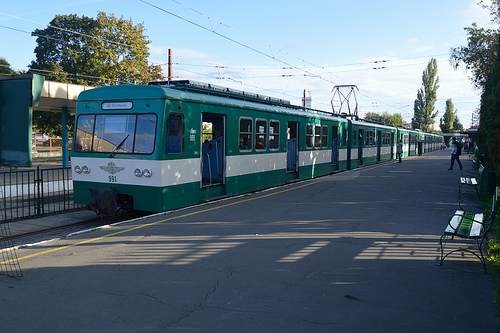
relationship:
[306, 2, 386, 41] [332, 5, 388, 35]
sky clear blue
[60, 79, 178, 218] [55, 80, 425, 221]
front of train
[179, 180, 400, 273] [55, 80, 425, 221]
platform for train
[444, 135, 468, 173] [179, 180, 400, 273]
person walking on a platform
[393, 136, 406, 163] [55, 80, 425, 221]
person about to board a train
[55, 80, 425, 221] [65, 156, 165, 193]
train has a white strip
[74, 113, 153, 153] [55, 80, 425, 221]
windshield on a train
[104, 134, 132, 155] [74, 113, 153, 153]
wipers on windshield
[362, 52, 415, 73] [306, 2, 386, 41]
cables in sky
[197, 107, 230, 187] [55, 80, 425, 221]
doorway to train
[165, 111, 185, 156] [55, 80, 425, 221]
window on a train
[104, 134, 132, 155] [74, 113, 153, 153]
wiper on windshield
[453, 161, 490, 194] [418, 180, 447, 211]
bench on concrete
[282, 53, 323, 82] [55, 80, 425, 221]
wires for train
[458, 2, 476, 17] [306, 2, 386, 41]
clouds in sky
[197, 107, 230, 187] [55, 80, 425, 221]
door to train